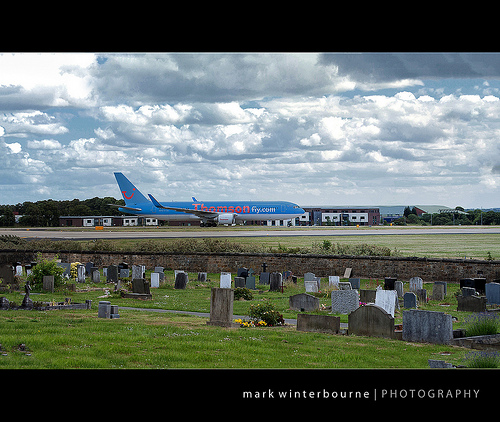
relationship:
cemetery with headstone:
[0, 249, 499, 368] [400, 308, 455, 349]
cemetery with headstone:
[0, 249, 499, 368] [346, 303, 399, 339]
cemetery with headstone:
[0, 249, 499, 368] [295, 311, 344, 337]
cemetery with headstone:
[0, 249, 499, 368] [204, 284, 239, 328]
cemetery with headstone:
[0, 249, 499, 368] [326, 287, 361, 316]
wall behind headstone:
[0, 248, 499, 289] [400, 308, 455, 349]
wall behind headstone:
[0, 248, 499, 289] [346, 303, 399, 339]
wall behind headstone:
[0, 248, 499, 289] [326, 287, 361, 316]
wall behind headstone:
[0, 248, 499, 289] [204, 284, 239, 328]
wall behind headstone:
[0, 248, 499, 289] [295, 311, 344, 337]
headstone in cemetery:
[400, 308, 455, 349] [0, 249, 499, 368]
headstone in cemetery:
[346, 303, 399, 339] [0, 249, 499, 368]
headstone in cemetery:
[295, 311, 344, 337] [0, 249, 499, 368]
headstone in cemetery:
[204, 284, 239, 328] [0, 249, 499, 368]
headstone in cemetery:
[372, 287, 399, 320] [0, 249, 499, 368]